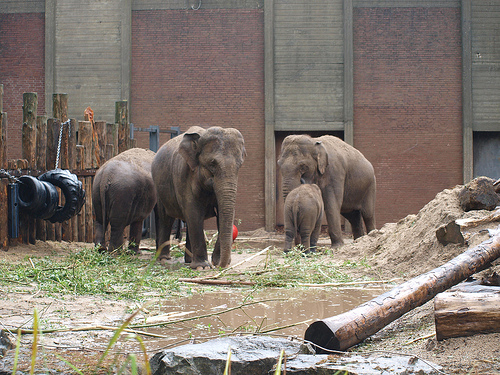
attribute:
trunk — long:
[209, 168, 240, 270]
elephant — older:
[271, 125, 383, 242]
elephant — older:
[152, 120, 253, 267]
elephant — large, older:
[89, 142, 159, 249]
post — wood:
[111, 97, 131, 123]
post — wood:
[58, 92, 71, 129]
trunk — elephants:
[196, 143, 249, 290]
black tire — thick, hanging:
[12, 175, 41, 212]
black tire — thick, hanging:
[28, 178, 58, 220]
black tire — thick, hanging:
[36, 169, 84, 224]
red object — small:
[231, 222, 240, 247]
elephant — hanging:
[276, 181, 328, 251]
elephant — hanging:
[95, 145, 154, 252]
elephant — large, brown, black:
[91, 143, 166, 257]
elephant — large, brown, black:
[274, 131, 383, 247]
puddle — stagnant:
[6, 281, 390, 371]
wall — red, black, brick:
[347, 0, 473, 240]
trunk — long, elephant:
[207, 169, 237, 262]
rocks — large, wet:
[162, 326, 438, 368]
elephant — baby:
[281, 178, 323, 255]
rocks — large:
[150, 332, 320, 374]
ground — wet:
[0, 227, 497, 372]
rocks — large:
[271, 350, 446, 372]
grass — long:
[0, 241, 367, 373]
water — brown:
[168, 245, 455, 352]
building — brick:
[186, 20, 491, 152]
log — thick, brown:
[310, 233, 452, 356]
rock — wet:
[157, 327, 402, 371]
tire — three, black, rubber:
[16, 169, 87, 221]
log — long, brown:
[302, 227, 499, 350]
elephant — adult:
[267, 130, 407, 255]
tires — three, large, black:
[12, 164, 86, 225]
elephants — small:
[167, 119, 369, 246]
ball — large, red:
[216, 219, 245, 250]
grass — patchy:
[36, 250, 316, 321]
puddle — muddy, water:
[3, 276, 499, 372]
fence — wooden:
[2, 82, 183, 245]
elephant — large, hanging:
[278, 131, 377, 249]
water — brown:
[4, 284, 395, 373]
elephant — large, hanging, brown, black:
[150, 122, 245, 275]